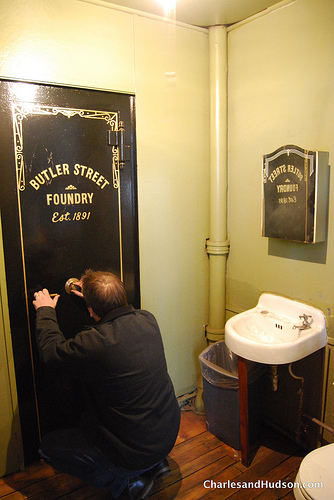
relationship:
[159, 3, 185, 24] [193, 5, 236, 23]
light on ceiling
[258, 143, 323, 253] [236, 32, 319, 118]
cabinet on wall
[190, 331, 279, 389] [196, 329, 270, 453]
bag in trash can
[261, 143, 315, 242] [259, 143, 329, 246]
mirror part of cabinet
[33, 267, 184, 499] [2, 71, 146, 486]
man trying to open safe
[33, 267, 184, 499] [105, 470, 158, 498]
man wearing shoe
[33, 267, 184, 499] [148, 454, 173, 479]
man wearing shoe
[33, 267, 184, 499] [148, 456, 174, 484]
man wearing shoe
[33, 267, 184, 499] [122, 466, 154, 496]
man wearing shoe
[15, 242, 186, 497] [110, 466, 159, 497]
man wearing shoe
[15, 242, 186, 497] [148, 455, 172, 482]
man wearing shoe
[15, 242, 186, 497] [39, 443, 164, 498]
man wearing jeans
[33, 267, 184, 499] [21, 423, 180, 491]
man wearing pants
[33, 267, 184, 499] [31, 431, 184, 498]
man wearing pants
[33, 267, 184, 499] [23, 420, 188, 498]
man wearing jeans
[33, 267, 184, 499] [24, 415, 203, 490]
man wearing jeans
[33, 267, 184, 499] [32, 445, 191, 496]
man wearing jeans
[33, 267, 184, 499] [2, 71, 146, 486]
man unlocking safe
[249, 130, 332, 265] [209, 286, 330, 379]
mirror above sink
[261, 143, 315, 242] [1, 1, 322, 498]
mirror in bathroom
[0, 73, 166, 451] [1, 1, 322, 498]
safe in bathroom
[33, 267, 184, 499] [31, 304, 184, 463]
man wearing jacket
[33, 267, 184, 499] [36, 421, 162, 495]
man wearing pants